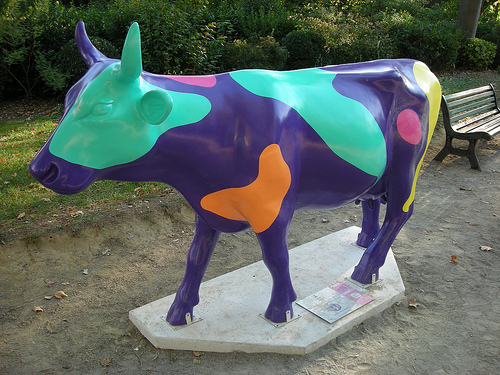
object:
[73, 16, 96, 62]
ear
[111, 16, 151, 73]
ear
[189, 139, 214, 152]
color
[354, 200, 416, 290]
leg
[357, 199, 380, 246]
leg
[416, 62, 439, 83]
color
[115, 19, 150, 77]
horn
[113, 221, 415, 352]
base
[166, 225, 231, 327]
leg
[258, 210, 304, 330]
leg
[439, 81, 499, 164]
bench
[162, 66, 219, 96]
circle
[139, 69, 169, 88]
back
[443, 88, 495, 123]
slats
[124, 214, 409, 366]
statue base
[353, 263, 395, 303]
plaque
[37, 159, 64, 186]
nostril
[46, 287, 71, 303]
leaf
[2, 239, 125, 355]
ground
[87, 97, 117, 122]
eye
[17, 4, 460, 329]
cow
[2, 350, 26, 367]
imprints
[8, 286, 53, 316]
dirt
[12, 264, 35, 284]
imprints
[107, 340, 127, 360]
dirt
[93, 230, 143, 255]
imprints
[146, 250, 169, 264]
imprints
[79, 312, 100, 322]
imprints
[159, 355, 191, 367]
imprints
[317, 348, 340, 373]
dirt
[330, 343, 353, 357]
imprints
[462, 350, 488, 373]
dirt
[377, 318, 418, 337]
imprints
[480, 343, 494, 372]
dirt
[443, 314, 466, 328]
imprints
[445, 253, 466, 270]
imprints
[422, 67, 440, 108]
yellow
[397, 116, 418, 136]
pink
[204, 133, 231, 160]
purple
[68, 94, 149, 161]
green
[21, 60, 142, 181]
face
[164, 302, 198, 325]
left foot